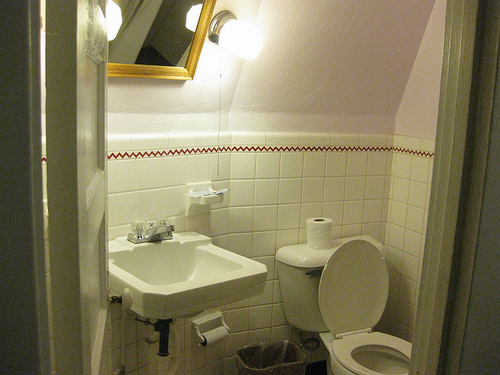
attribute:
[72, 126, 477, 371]
bathroom — small, tiled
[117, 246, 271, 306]
sink — white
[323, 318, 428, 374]
toilet — open, white, up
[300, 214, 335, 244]
toilet paper — white, roll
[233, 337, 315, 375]
garbage can — small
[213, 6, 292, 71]
light — on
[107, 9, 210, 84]
mirror — framed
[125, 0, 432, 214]
wall — white, tiled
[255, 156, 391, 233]
tile — white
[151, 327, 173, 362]
pipe — black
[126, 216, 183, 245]
faucet — silver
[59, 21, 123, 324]
door — open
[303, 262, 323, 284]
handle — silver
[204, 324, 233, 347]
roll — full, empty, hanging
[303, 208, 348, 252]
toilet tissue — empty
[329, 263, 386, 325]
lid — up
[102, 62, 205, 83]
frame — gold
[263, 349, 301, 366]
bag — plastic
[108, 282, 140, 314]
doorknob — white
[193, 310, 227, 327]
holder — white, ceramic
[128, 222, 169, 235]
fixtures — silver, clear